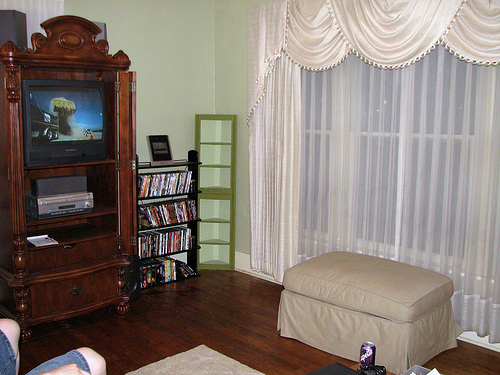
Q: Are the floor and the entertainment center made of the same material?
A: Yes, both the floor and the entertainment center are made of wood.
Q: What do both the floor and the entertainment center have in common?
A: The material, both the floor and the entertainment center are wooden.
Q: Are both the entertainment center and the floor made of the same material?
A: Yes, both the entertainment center and the floor are made of wood.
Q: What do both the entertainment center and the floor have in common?
A: The material, both the entertainment center and the floor are wooden.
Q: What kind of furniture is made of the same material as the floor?
A: The entertainment center is made of the same material as the floor.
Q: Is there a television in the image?
A: Yes, there is a television.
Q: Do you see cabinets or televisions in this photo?
A: Yes, there is a television.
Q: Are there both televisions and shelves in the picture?
A: Yes, there are both a television and a shelf.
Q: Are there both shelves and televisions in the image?
A: Yes, there are both a television and a shelf.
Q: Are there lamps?
A: No, there are no lamps.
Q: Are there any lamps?
A: No, there are no lamps.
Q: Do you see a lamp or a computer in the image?
A: No, there are no lamps or computers.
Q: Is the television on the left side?
A: Yes, the television is on the left of the image.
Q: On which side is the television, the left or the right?
A: The television is on the left of the image.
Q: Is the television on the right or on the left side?
A: The television is on the left of the image.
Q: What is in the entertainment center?
A: The TV is in the entertainment center.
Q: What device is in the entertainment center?
A: The device is a television.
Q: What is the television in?
A: The television is in the entertainment center.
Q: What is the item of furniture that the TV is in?
A: The piece of furniture is an entertainment center.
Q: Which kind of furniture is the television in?
A: The TV is in the entertainment center.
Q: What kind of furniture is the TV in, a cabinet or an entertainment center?
A: The TV is in an entertainment center.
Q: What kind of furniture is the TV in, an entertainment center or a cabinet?
A: The TV is in an entertainment center.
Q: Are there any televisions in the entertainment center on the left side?
A: Yes, there is a television in the entertainment center.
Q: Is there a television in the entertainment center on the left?
A: Yes, there is a television in the entertainment center.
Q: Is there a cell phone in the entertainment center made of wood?
A: No, there is a television in the entertainment center.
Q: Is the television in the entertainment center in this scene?
A: Yes, the television is in the entertainment center.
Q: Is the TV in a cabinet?
A: No, the TV is in the entertainment center.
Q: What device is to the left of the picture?
A: The device is a television.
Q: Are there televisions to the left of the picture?
A: Yes, there is a television to the left of the picture.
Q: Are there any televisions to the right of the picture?
A: No, the television is to the left of the picture.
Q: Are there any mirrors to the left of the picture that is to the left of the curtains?
A: No, there is a television to the left of the picture.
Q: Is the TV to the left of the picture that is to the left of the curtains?
A: Yes, the TV is to the left of the picture.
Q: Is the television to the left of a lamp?
A: No, the television is to the left of the picture.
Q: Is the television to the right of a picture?
A: No, the television is to the left of a picture.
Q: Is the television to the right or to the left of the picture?
A: The television is to the left of the picture.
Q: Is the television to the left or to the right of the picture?
A: The television is to the left of the picture.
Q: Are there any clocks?
A: No, there are no clocks.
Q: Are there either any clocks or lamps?
A: No, there are no clocks or lamps.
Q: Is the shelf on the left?
A: Yes, the shelf is on the left of the image.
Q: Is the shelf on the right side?
A: No, the shelf is on the left of the image.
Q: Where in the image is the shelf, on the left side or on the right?
A: The shelf is on the left of the image.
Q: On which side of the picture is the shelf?
A: The shelf is on the left of the image.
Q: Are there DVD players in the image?
A: Yes, there is a DVD player.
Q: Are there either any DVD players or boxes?
A: Yes, there is a DVD player.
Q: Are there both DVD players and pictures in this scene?
A: Yes, there are both a DVD player and a picture.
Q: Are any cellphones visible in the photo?
A: No, there are no cellphones.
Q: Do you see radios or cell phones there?
A: No, there are no cell phones or radios.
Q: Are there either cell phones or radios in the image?
A: No, there are no cell phones or radios.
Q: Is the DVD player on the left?
A: Yes, the DVD player is on the left of the image.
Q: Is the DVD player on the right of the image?
A: No, the DVD player is on the left of the image.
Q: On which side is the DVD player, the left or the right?
A: The DVD player is on the left of the image.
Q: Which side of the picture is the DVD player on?
A: The DVD player is on the left of the image.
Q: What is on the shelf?
A: The DVD player is on the shelf.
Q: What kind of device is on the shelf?
A: The device is a DVD player.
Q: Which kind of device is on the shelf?
A: The device is a DVD player.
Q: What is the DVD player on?
A: The DVD player is on the shelf.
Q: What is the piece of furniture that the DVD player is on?
A: The piece of furniture is a shelf.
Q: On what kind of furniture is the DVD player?
A: The DVD player is on the shelf.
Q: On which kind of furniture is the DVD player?
A: The DVD player is on the shelf.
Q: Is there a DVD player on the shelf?
A: Yes, there is a DVD player on the shelf.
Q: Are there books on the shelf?
A: No, there is a DVD player on the shelf.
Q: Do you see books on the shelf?
A: No, there is a DVD player on the shelf.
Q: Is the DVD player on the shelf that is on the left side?
A: Yes, the DVD player is on the shelf.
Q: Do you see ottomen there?
A: Yes, there is an ottoman.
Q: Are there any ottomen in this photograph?
A: Yes, there is an ottoman.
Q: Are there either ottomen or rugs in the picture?
A: Yes, there is an ottoman.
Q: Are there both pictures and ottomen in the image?
A: Yes, there are both an ottoman and a picture.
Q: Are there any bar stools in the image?
A: No, there are no bar stools.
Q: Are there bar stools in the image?
A: No, there are no bar stools.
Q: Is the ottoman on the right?
A: Yes, the ottoman is on the right of the image.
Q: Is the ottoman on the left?
A: No, the ottoman is on the right of the image.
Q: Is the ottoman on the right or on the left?
A: The ottoman is on the right of the image.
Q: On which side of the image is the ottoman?
A: The ottoman is on the right of the image.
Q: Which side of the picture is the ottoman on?
A: The ottoman is on the right of the image.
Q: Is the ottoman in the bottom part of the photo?
A: Yes, the ottoman is in the bottom of the image.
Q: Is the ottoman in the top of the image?
A: No, the ottoman is in the bottom of the image.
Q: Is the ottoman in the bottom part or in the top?
A: The ottoman is in the bottom of the image.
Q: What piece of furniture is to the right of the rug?
A: The piece of furniture is an ottoman.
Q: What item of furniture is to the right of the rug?
A: The piece of furniture is an ottoman.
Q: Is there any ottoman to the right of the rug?
A: Yes, there is an ottoman to the right of the rug.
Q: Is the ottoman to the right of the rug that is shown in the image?
A: Yes, the ottoman is to the right of the rug.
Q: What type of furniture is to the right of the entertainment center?
A: The piece of furniture is an ottoman.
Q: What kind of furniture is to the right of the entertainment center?
A: The piece of furniture is an ottoman.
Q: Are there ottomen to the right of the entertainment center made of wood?
A: Yes, there is an ottoman to the right of the entertainment center.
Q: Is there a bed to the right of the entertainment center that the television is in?
A: No, there is an ottoman to the right of the entertainment center.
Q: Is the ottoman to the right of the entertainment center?
A: Yes, the ottoman is to the right of the entertainment center.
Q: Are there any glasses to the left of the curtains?
A: No, there are DVDs to the left of the curtains.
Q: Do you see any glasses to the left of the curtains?
A: No, there are DVDs to the left of the curtains.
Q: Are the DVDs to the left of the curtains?
A: Yes, the DVDs are to the left of the curtains.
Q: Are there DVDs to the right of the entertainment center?
A: Yes, there are DVDs to the right of the entertainment center.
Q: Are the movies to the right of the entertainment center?
A: Yes, the movies are to the right of the entertainment center.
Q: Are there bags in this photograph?
A: No, there are no bags.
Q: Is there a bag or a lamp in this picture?
A: No, there are no bags or lamps.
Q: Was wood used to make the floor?
A: Yes, the floor is made of wood.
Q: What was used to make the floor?
A: The floor is made of wood.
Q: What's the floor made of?
A: The floor is made of wood.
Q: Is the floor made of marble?
A: No, the floor is made of wood.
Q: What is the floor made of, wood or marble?
A: The floor is made of wood.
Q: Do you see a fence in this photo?
A: No, there are no fences.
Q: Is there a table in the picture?
A: Yes, there is a table.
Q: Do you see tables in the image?
A: Yes, there is a table.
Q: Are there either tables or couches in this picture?
A: Yes, there is a table.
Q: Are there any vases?
A: No, there are no vases.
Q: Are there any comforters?
A: No, there are no comforters.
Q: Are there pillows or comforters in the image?
A: No, there are no comforters or pillows.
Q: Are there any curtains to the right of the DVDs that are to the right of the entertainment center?
A: Yes, there are curtains to the right of the movies.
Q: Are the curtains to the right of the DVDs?
A: Yes, the curtains are to the right of the DVDs.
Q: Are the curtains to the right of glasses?
A: No, the curtains are to the right of the DVDs.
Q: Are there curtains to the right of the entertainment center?
A: Yes, there are curtains to the right of the entertainment center.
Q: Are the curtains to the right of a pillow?
A: No, the curtains are to the right of the entertainment center.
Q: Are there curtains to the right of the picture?
A: Yes, there are curtains to the right of the picture.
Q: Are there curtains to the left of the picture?
A: No, the curtains are to the right of the picture.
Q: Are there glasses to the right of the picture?
A: No, there are curtains to the right of the picture.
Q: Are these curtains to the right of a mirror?
A: No, the curtains are to the right of the picture.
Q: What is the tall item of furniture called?
A: The piece of furniture is an entertainment center.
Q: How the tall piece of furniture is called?
A: The piece of furniture is an entertainment center.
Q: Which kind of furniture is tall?
A: The furniture is an entertainment center.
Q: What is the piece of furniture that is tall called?
A: The piece of furniture is an entertainment center.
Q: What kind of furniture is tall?
A: The furniture is an entertainment center.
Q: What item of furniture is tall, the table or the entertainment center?
A: The entertainment center is tall.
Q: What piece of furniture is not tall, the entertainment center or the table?
A: The table is not tall.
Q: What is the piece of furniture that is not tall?
A: The piece of furniture is a table.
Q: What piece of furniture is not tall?
A: The piece of furniture is a table.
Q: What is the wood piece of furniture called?
A: The piece of furniture is an entertainment center.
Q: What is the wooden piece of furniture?
A: The piece of furniture is an entertainment center.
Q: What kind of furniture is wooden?
A: The furniture is an entertainment center.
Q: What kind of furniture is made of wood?
A: The furniture is an entertainment center.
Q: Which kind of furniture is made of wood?
A: The furniture is an entertainment center.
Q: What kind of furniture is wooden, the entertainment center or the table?
A: The entertainment center is wooden.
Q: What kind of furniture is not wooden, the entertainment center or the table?
A: The table is not wooden.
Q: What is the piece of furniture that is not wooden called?
A: The piece of furniture is a table.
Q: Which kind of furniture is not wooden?
A: The furniture is a table.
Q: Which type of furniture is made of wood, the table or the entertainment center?
A: The entertainment center is made of wood.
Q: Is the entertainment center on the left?
A: Yes, the entertainment center is on the left of the image.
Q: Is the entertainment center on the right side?
A: No, the entertainment center is on the left of the image.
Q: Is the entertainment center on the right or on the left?
A: The entertainment center is on the left of the image.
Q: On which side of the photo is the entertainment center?
A: The entertainment center is on the left of the image.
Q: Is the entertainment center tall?
A: Yes, the entertainment center is tall.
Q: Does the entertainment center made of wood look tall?
A: Yes, the entertainment center is tall.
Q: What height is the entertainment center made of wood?
A: The entertainment center is tall.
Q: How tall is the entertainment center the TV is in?
A: The entertainment center is tall.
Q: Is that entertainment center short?
A: No, the entertainment center is tall.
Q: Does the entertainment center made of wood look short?
A: No, the entertainment center is tall.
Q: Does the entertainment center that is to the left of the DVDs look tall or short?
A: The entertainment center is tall.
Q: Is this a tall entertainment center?
A: Yes, this is a tall entertainment center.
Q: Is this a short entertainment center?
A: No, this is a tall entertainment center.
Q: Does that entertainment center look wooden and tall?
A: Yes, the entertainment center is wooden and tall.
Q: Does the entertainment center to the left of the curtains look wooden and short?
A: No, the entertainment center is wooden but tall.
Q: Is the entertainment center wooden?
A: Yes, the entertainment center is wooden.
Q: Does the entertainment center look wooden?
A: Yes, the entertainment center is wooden.